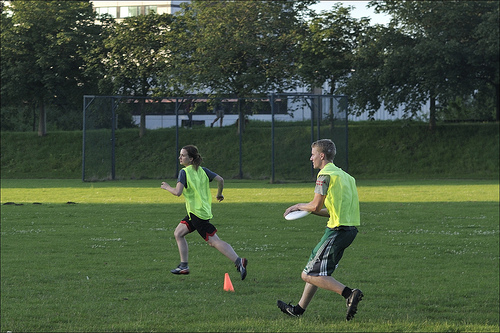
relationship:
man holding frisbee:
[274, 137, 367, 323] [280, 211, 313, 225]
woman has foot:
[157, 142, 250, 283] [237, 256, 249, 281]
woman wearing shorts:
[157, 142, 250, 283] [178, 212, 223, 241]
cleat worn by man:
[273, 296, 306, 319] [274, 137, 367, 323]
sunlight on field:
[3, 182, 500, 208] [1, 176, 500, 332]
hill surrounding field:
[2, 121, 500, 179] [1, 176, 500, 332]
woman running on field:
[157, 142, 250, 283] [1, 176, 500, 332]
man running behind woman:
[274, 137, 367, 323] [157, 142, 250, 283]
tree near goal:
[169, 2, 309, 125] [77, 91, 352, 186]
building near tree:
[4, 1, 481, 131] [169, 2, 309, 125]